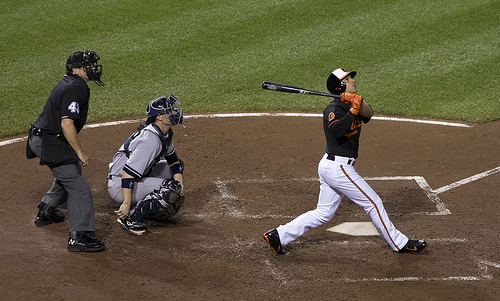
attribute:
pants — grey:
[107, 160, 176, 203]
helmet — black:
[140, 93, 177, 122]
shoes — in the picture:
[116, 214, 152, 239]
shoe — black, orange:
[399, 237, 427, 252]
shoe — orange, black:
[263, 227, 285, 254]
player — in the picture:
[336, 86, 364, 107]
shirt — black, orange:
[319, 88, 379, 163]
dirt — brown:
[183, 124, 318, 211]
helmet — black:
[154, 94, 196, 135]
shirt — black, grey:
[120, 127, 179, 192]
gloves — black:
[337, 90, 364, 122]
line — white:
[212, 172, 427, 185]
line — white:
[413, 174, 452, 216]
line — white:
[231, 209, 450, 221]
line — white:
[212, 177, 242, 218]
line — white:
[431, 165, 499, 195]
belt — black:
[317, 147, 364, 167]